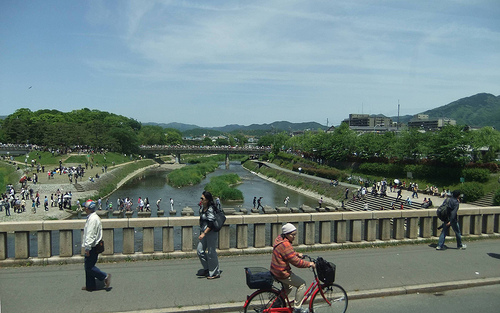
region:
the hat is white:
[275, 210, 332, 255]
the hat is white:
[265, 216, 301, 241]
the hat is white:
[261, 205, 293, 237]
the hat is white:
[267, 220, 313, 255]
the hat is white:
[260, 190, 301, 246]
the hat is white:
[267, 224, 299, 278]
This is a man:
[80, 200, 111, 292]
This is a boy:
[268, 220, 319, 310]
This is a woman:
[187, 185, 227, 280]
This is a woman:
[432, 185, 464, 255]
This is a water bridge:
[0, 201, 495, 306]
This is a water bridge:
[16, 130, 466, 170]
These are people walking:
[0, 125, 495, 275]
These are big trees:
[0, 105, 495, 175]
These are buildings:
[340, 105, 465, 137]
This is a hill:
[404, 84, 498, 133]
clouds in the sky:
[111, 23, 241, 69]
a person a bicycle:
[243, 215, 349, 310]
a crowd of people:
[10, 186, 57, 213]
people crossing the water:
[99, 192, 163, 217]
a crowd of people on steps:
[358, 176, 387, 199]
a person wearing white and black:
[67, 194, 120, 285]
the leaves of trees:
[68, 114, 102, 137]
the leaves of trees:
[339, 127, 383, 152]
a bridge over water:
[162, 142, 252, 160]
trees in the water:
[157, 164, 200, 195]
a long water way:
[109, 127, 349, 236]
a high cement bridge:
[138, 125, 281, 169]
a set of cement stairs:
[322, 151, 432, 238]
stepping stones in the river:
[60, 192, 198, 219]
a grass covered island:
[162, 145, 233, 192]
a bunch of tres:
[5, 100, 178, 164]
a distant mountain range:
[145, 107, 330, 143]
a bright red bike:
[233, 254, 358, 311]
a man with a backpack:
[434, 176, 479, 258]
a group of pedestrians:
[6, 160, 109, 216]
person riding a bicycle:
[243, 228, 338, 303]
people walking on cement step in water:
[100, 191, 188, 217]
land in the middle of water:
[213, 147, 250, 217]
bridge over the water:
[315, 203, 428, 288]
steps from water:
[352, 185, 424, 219]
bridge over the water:
[137, 126, 285, 173]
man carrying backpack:
[428, 187, 478, 257]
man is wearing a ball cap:
[74, 194, 124, 229]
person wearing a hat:
[270, 214, 307, 244]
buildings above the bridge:
[343, 95, 443, 143]